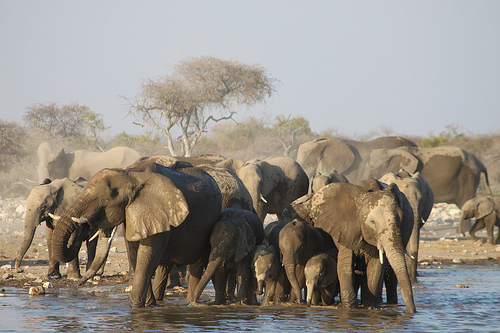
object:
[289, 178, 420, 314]
elephants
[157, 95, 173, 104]
leaves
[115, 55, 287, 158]
tree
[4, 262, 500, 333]
water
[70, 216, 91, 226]
tusks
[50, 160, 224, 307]
elephant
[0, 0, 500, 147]
sky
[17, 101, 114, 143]
trees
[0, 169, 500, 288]
ground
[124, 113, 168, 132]
branches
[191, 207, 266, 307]
elephant\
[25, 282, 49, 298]
rocks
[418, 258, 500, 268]
mud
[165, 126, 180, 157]
trunks